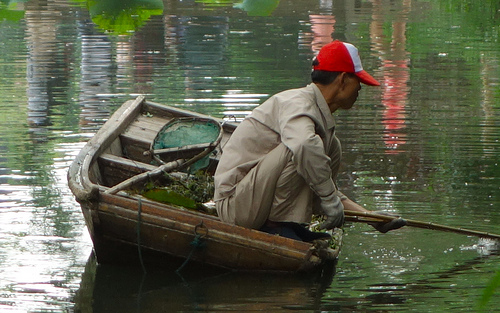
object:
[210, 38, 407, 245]
man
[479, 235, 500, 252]
net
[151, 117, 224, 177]
net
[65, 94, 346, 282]
boat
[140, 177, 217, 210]
plants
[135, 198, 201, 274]
rope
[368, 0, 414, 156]
reflection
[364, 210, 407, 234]
gloves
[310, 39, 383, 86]
baseball cap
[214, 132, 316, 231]
pants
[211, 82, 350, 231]
suit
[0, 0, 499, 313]
water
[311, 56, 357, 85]
hair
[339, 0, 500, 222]
shadow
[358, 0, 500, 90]
reflections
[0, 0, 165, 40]
plants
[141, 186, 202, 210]
leaf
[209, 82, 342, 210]
shirt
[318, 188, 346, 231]
glove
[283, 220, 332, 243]
shoes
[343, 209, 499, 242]
fishing rod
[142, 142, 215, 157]
stick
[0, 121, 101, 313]
light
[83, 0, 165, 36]
leaf